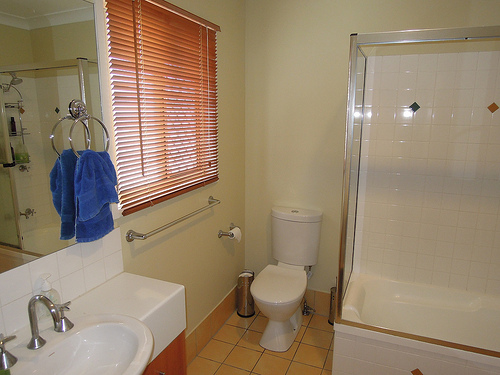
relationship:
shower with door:
[299, 19, 493, 372] [338, 28, 497, 362]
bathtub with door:
[326, 264, 496, 373] [338, 28, 497, 362]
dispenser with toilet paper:
[219, 220, 245, 241] [228, 227, 243, 242]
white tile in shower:
[431, 103, 452, 125] [330, 37, 498, 374]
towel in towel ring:
[71, 155, 113, 218] [69, 115, 111, 158]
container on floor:
[219, 266, 273, 320] [183, 301, 329, 373]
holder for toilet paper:
[217, 222, 238, 242] [231, 226, 245, 241]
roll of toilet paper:
[227, 227, 243, 241] [231, 227, 241, 241]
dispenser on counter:
[40, 271, 60, 331] [0, 229, 185, 374]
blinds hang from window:
[104, 0, 268, 202] [107, 0, 216, 207]